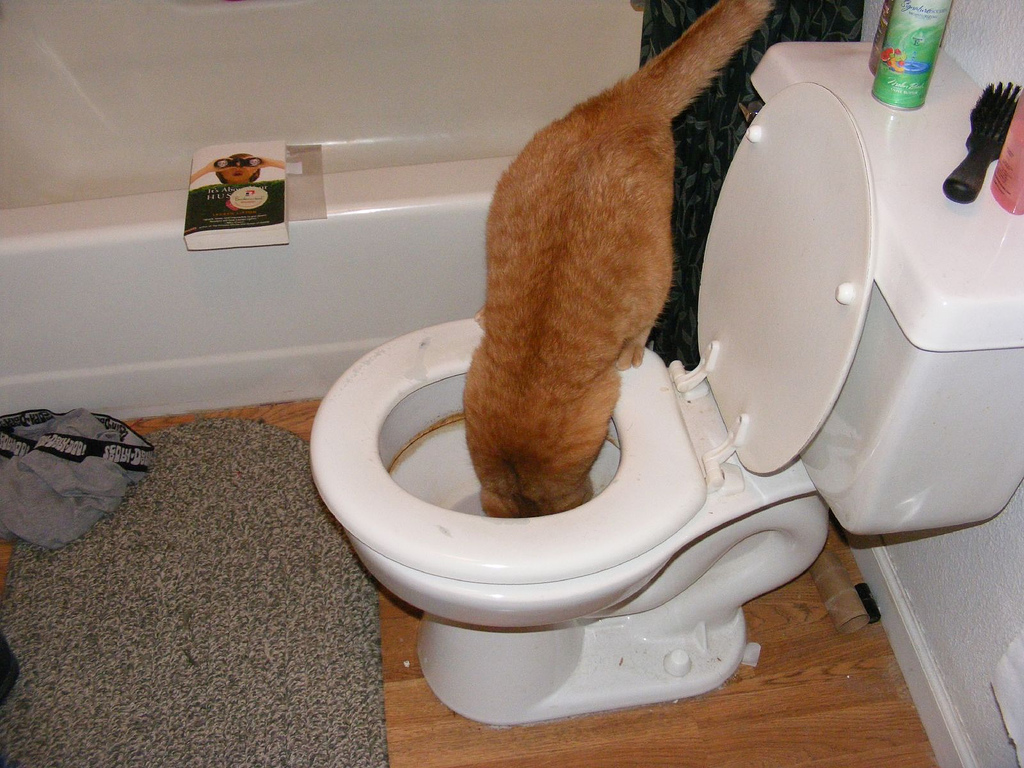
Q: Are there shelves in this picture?
A: No, there are no shelves.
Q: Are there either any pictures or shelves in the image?
A: No, there are no shelves or pictures.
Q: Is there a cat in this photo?
A: Yes, there is a cat.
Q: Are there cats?
A: Yes, there is a cat.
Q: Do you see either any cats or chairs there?
A: Yes, there is a cat.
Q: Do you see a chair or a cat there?
A: Yes, there is a cat.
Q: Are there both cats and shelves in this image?
A: No, there is a cat but no shelves.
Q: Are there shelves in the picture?
A: No, there are no shelves.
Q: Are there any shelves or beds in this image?
A: No, there are no shelves or beds.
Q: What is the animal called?
A: The animal is a cat.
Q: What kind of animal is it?
A: The animal is a cat.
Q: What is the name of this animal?
A: This is a cat.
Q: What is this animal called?
A: This is a cat.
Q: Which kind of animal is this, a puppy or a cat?
A: This is a cat.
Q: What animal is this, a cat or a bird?
A: This is a cat.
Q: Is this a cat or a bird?
A: This is a cat.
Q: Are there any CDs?
A: No, there are no cds.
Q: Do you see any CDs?
A: No, there are no cds.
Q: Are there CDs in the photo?
A: No, there are no cds.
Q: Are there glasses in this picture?
A: No, there are no glasses.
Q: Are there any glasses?
A: No, there are no glasses.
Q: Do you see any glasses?
A: No, there are no glasses.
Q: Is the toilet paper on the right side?
A: Yes, the toilet paper is on the right of the image.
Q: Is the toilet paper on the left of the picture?
A: No, the toilet paper is on the right of the image.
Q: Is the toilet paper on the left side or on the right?
A: The toilet paper is on the right of the image.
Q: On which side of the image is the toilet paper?
A: The toilet paper is on the right of the image.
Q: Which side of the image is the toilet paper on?
A: The toilet paper is on the right of the image.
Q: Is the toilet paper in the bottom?
A: Yes, the toilet paper is in the bottom of the image.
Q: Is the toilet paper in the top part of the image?
A: No, the toilet paper is in the bottom of the image.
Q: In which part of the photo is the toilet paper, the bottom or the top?
A: The toilet paper is in the bottom of the image.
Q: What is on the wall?
A: The toilet paper is on the wall.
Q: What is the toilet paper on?
A: The toilet paper is on the wall.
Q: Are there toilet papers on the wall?
A: Yes, there is a toilet paper on the wall.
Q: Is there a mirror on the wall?
A: No, there is a toilet paper on the wall.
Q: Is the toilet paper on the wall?
A: Yes, the toilet paper is on the wall.